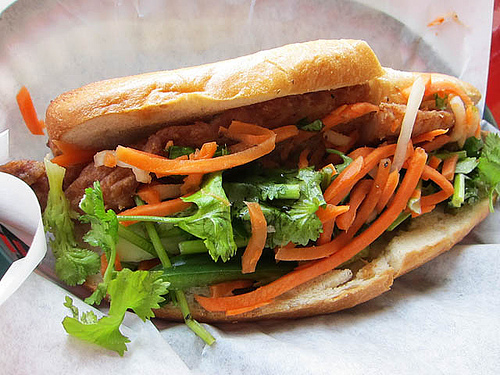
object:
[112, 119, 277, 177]
carrot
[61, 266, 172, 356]
lettuce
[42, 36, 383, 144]
bun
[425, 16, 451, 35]
sauce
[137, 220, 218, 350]
stick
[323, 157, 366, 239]
carrot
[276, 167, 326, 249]
lettuce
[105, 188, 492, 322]
bread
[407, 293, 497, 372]
paper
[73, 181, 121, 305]
parsley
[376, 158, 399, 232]
carrot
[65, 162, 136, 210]
meat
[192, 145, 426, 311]
carrot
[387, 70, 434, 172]
onion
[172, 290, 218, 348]
stem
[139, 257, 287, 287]
bell pepper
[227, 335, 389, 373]
paper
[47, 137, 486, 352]
vegetables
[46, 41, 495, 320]
sandwich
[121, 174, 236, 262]
lettuce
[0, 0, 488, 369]
parchment paper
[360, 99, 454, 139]
meat